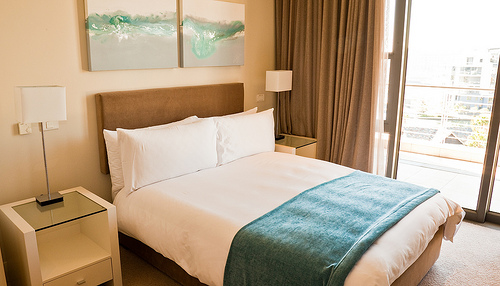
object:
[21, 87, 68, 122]
shade of lamp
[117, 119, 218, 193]
pillow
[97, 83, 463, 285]
bed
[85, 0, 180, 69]
painting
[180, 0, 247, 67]
painting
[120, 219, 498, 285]
carpet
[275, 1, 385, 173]
curtain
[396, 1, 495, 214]
window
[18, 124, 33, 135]
light switch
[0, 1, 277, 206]
wall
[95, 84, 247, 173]
head board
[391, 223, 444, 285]
foot board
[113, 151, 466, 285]
linen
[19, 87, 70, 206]
lamp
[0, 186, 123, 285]
nightstand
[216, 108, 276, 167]
pillow